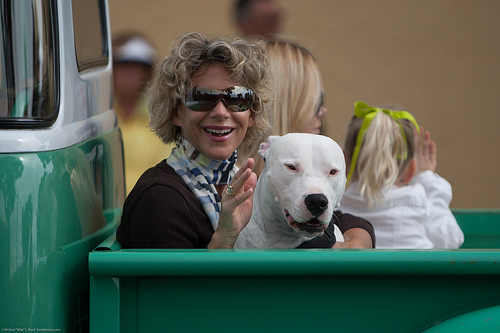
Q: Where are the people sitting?
A: Truck.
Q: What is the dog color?
A: White.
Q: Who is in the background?
A: Male.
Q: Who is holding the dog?
A: Female.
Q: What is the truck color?
A: Turqouise.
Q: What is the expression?
A: Smiling.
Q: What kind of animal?
A: Dog.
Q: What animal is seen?
A: A white dog.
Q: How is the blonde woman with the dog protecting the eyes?
A: With sunglasses.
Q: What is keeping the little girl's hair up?
A: A yellow ribbon in a bow.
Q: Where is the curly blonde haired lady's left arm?
A: Wrapped around the dog.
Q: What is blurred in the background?
A: Two people standing.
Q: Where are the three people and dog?
A: Sitting in the bed of a truck.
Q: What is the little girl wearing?
A: A white jacket.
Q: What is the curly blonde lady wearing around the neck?
A: A scarf.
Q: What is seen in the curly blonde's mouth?
A: White teeth.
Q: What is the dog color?
A: White.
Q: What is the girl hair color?
A: Blonde.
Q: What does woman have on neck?
A: Scarf.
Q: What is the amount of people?
A: Three people.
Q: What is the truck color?
A: Green.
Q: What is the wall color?
A: Brown.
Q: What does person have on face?
A: Glasses.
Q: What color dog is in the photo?
A: White.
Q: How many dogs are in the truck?
A: One.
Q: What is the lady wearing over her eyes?
A: Sunglasses.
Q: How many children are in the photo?
A: One.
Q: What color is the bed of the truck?
A: Green.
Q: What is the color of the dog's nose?
A: Black.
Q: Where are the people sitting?
A: The bed of a truck.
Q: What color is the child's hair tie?
A: Yellow.